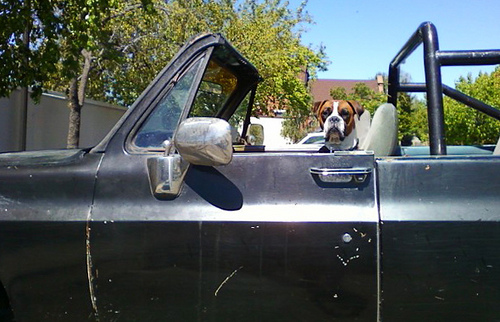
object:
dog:
[310, 98, 365, 153]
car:
[0, 20, 500, 322]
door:
[82, 33, 381, 321]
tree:
[0, 0, 58, 150]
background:
[2, 2, 500, 151]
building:
[239, 58, 385, 120]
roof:
[256, 75, 382, 111]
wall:
[0, 82, 129, 157]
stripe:
[323, 101, 345, 138]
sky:
[0, 0, 500, 111]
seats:
[360, 102, 398, 157]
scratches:
[212, 268, 240, 298]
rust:
[84, 208, 100, 312]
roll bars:
[383, 19, 500, 158]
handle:
[309, 166, 373, 175]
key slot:
[354, 175, 366, 182]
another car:
[291, 131, 323, 145]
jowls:
[324, 125, 346, 144]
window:
[123, 47, 210, 157]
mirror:
[145, 114, 236, 198]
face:
[310, 99, 366, 145]